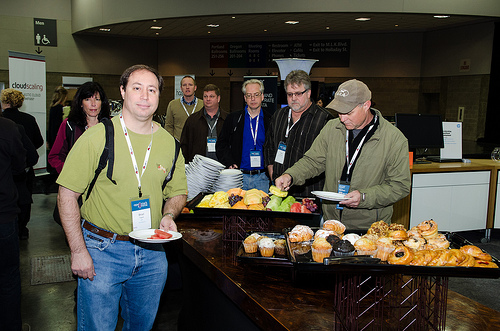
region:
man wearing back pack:
[27, 56, 184, 314]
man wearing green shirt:
[58, 60, 188, 327]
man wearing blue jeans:
[60, 57, 188, 322]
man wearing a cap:
[315, 76, 415, 224]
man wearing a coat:
[337, 77, 408, 212]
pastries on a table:
[370, 215, 476, 267]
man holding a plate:
[95, 65, 181, 280]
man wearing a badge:
[102, 66, 177, 308]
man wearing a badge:
[197, 81, 229, 151]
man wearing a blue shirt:
[233, 80, 273, 164]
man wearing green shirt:
[45, 50, 203, 291]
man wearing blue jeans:
[35, 201, 205, 329]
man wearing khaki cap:
[311, 67, 405, 138]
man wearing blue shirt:
[228, 67, 288, 187]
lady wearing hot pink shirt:
[29, 62, 120, 164]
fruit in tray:
[187, 173, 329, 238]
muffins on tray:
[238, 210, 290, 270]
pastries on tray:
[285, 224, 499, 284]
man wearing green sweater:
[159, 63, 214, 153]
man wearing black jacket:
[161, 70, 254, 178]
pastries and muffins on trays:
[235, 213, 499, 284]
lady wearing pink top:
[39, 69, 114, 191]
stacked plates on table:
[185, 144, 255, 212]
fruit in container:
[196, 181, 339, 231]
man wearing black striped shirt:
[254, 75, 351, 193]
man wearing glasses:
[266, 80, 318, 180]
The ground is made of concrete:
[28, 288, 68, 327]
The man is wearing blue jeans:
[68, 222, 172, 328]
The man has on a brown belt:
[73, 216, 131, 248]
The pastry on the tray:
[287, 221, 499, 283]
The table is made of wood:
[239, 274, 317, 324]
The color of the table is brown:
[241, 275, 316, 322]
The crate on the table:
[328, 280, 455, 329]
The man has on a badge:
[114, 115, 162, 233]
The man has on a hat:
[321, 77, 378, 118]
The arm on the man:
[51, 124, 99, 284]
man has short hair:
[115, 66, 154, 90]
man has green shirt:
[85, 116, 194, 228]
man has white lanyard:
[100, 123, 168, 238]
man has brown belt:
[83, 212, 138, 252]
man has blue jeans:
[80, 225, 183, 327]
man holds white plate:
[140, 224, 176, 243]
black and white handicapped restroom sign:
[18, 18, 60, 46]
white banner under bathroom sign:
[5, 54, 57, 195]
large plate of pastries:
[242, 227, 499, 262]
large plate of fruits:
[207, 176, 350, 221]